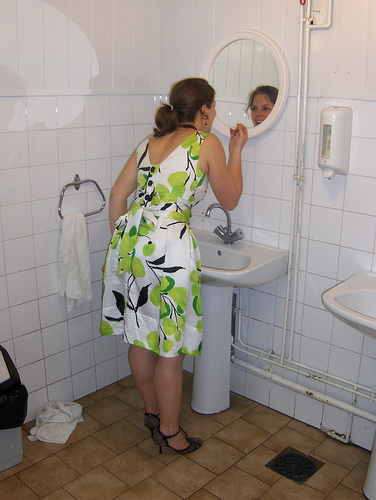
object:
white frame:
[198, 31, 291, 140]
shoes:
[152, 426, 202, 455]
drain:
[266, 441, 325, 485]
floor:
[0, 358, 374, 500]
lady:
[99, 76, 248, 456]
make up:
[169, 33, 282, 141]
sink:
[188, 229, 291, 288]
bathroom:
[0, 0, 376, 499]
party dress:
[98, 124, 209, 357]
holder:
[58, 178, 107, 219]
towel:
[57, 213, 94, 312]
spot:
[0, 0, 100, 137]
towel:
[27, 399, 84, 444]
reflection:
[245, 85, 279, 127]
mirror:
[198, 29, 291, 140]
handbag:
[0, 345, 29, 431]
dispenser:
[318, 106, 353, 181]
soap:
[321, 125, 331, 160]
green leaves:
[167, 171, 187, 187]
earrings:
[204, 115, 210, 128]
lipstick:
[237, 124, 245, 128]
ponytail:
[152, 102, 179, 137]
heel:
[159, 446, 163, 454]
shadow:
[287, 205, 361, 290]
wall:
[0, 0, 376, 456]